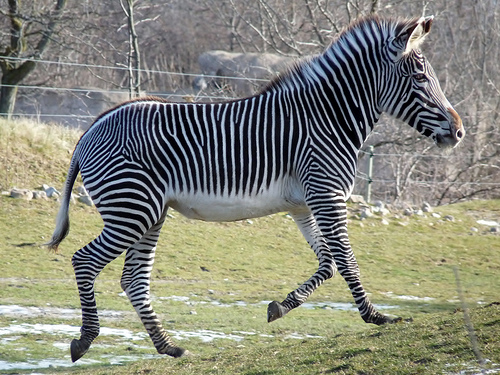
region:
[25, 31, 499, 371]
the zebra is running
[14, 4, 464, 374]
zebra's fur is stripes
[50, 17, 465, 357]
Zebra running in the pasture.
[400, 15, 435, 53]
The zebra's ears.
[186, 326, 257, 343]
Snow on the ground.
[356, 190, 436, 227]
Rocks and pebbles line the fence.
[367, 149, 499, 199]
Cable fence to protect the zebra.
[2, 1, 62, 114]
Bare winter trees.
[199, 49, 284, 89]
Another animal in the background.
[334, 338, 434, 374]
Grass for the zebra to munch on.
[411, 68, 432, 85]
Zebra's eye.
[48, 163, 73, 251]
Zebra's tail.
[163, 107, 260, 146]
Black and white stripes of the zebra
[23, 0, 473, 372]
A zebra standing in the forest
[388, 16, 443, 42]
Large upright ears of the zebra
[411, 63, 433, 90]
Eye of the zebra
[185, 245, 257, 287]
Green color grass in the forest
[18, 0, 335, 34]
Lot of trees with its branches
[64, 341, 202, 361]
Hoofs of the zebra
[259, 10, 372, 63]
Black and white mane of the zebra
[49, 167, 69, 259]
Tail of the zebra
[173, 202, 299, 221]
Under belly of the zebra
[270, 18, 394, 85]
zebra's striped mane on neck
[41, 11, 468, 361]
zebra trotting across green field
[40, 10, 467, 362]
zebra runninging across grass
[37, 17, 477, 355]
zebra walking across field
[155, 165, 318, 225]
zebra's white colored belly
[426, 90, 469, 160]
zebra's brown topped muzzle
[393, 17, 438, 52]
zebra's erect striped ears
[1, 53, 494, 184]
barbed wire fence behind zebra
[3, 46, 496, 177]
wire fence behind zebra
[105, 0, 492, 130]
bare trees beyond wire fence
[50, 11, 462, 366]
A zebra walks along the grass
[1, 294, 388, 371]
Patches of snow on the ground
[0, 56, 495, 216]
A wired fence in the park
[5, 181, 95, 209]
Rocks piled on the ground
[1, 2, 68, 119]
A tree in the park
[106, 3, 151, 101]
Two leafless trees in the park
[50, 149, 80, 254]
A zebra's tail wags behind him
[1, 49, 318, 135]
A rock formation in the park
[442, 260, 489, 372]
A twig stands upright in the grass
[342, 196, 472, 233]
A cluster of rocks near the fence